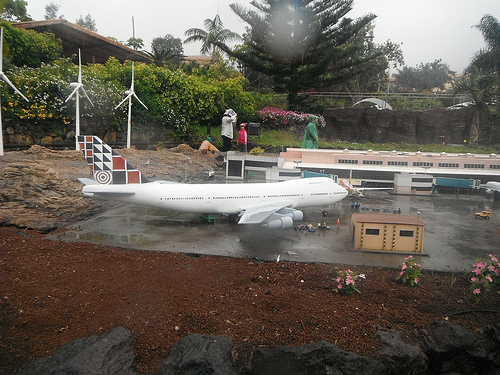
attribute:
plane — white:
[45, 155, 362, 236]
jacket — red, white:
[211, 115, 244, 141]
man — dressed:
[202, 104, 245, 158]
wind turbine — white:
[261, 206, 310, 244]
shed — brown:
[337, 201, 447, 268]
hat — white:
[214, 108, 246, 118]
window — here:
[270, 189, 301, 206]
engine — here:
[260, 218, 300, 240]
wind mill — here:
[120, 59, 146, 166]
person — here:
[298, 110, 328, 156]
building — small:
[336, 199, 450, 285]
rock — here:
[291, 268, 316, 288]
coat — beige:
[222, 115, 237, 135]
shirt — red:
[236, 129, 255, 144]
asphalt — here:
[122, 214, 244, 262]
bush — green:
[142, 68, 263, 142]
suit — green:
[302, 128, 326, 146]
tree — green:
[231, 5, 407, 129]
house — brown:
[339, 205, 461, 266]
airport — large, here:
[76, 148, 496, 235]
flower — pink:
[332, 261, 362, 297]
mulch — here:
[95, 290, 446, 362]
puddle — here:
[431, 211, 496, 266]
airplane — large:
[81, 126, 398, 239]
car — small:
[462, 204, 497, 236]